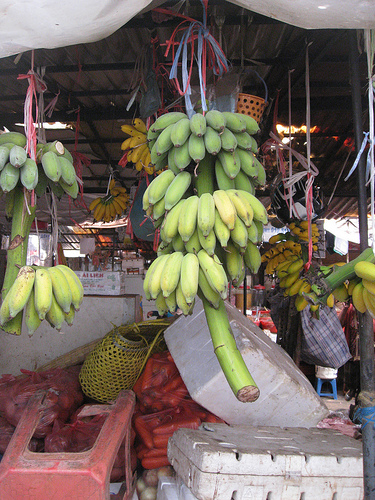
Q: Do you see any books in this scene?
A: No, there are no books.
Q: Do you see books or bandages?
A: No, there are no books or bandages.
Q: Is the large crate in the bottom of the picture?
A: Yes, the crate is in the bottom of the image.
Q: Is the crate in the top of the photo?
A: No, the crate is in the bottom of the image.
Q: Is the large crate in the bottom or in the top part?
A: The crate is in the bottom of the image.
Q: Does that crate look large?
A: Yes, the crate is large.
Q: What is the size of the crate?
A: The crate is large.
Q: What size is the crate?
A: The crate is large.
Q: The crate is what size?
A: The crate is large.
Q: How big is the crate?
A: The crate is large.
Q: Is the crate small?
A: No, the crate is large.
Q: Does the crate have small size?
A: No, the crate is large.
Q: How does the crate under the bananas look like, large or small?
A: The crate is large.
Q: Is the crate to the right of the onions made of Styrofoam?
A: Yes, the crate is made of styrofoam.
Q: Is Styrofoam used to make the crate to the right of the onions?
A: Yes, the crate is made of styrofoam.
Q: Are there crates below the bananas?
A: Yes, there is a crate below the bananas.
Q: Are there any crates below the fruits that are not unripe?
A: Yes, there is a crate below the bananas.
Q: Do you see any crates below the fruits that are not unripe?
A: Yes, there is a crate below the bananas.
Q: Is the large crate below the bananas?
A: Yes, the crate is below the bananas.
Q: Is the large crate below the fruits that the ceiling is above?
A: Yes, the crate is below the bananas.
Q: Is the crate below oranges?
A: No, the crate is below the bananas.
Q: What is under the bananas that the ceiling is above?
A: The crate is under the bananas.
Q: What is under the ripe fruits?
A: The crate is under the bananas.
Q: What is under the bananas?
A: The crate is under the bananas.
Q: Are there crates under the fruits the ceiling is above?
A: Yes, there is a crate under the bananas.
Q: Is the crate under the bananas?
A: Yes, the crate is under the bananas.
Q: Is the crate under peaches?
A: No, the crate is under the bananas.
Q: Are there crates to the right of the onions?
A: Yes, there is a crate to the right of the onions.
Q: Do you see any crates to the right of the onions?
A: Yes, there is a crate to the right of the onions.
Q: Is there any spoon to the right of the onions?
A: No, there is a crate to the right of the onions.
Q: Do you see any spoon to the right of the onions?
A: No, there is a crate to the right of the onions.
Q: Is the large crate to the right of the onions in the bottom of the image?
A: Yes, the crate is to the right of the onions.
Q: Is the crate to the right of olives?
A: No, the crate is to the right of the onions.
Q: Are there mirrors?
A: No, there are no mirrors.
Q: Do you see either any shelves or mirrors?
A: No, there are no mirrors or shelves.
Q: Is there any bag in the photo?
A: Yes, there is a bag.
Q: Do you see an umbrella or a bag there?
A: Yes, there is a bag.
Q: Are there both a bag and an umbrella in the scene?
A: No, there is a bag but no umbrellas.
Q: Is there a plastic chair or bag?
A: Yes, there is a plastic bag.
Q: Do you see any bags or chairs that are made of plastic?
A: Yes, the bag is made of plastic.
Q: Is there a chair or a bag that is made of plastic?
A: Yes, the bag is made of plastic.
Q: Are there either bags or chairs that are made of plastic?
A: Yes, the bag is made of plastic.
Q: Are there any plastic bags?
A: Yes, there is a bag that is made of plastic.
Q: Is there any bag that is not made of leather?
A: Yes, there is a bag that is made of plastic.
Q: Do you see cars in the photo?
A: No, there are no cars.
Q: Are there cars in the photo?
A: No, there are no cars.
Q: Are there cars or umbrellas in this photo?
A: No, there are no cars or umbrellas.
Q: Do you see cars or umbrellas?
A: No, there are no cars or umbrellas.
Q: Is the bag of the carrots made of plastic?
A: Yes, the bag is made of plastic.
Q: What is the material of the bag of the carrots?
A: The bag is made of plastic.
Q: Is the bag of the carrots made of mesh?
A: No, the bag is made of plastic.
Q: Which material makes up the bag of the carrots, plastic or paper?
A: The bag is made of plastic.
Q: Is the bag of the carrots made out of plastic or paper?
A: The bag is made of plastic.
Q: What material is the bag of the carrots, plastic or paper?
A: The bag is made of plastic.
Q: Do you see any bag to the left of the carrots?
A: Yes, there is a bag to the left of the carrots.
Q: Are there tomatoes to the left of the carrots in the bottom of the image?
A: No, there is a bag to the left of the carrots.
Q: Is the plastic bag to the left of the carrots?
A: Yes, the bag is to the left of the carrots.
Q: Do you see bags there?
A: Yes, there is a bag.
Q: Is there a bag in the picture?
A: Yes, there is a bag.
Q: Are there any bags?
A: Yes, there is a bag.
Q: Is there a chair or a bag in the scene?
A: Yes, there is a bag.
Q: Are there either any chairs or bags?
A: Yes, there is a bag.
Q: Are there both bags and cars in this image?
A: No, there is a bag but no cars.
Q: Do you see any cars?
A: No, there are no cars.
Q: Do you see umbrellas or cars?
A: No, there are no cars or umbrellas.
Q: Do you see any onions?
A: Yes, there are onions.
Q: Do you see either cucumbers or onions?
A: Yes, there are onions.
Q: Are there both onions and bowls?
A: No, there are onions but no bowls.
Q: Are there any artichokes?
A: No, there are no artichokes.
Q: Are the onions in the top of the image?
A: No, the onions are in the bottom of the image.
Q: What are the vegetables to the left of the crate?
A: The vegetables are onions.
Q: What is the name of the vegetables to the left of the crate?
A: The vegetables are onions.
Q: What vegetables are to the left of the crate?
A: The vegetables are onions.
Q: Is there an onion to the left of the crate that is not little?
A: Yes, there are onions to the left of the crate.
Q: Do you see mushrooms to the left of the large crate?
A: No, there are onions to the left of the crate.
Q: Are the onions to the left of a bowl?
A: No, the onions are to the left of the crate.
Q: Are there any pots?
A: No, there are no pots.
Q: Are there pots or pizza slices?
A: No, there are no pots or pizza slices.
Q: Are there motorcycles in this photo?
A: No, there are no motorcycles.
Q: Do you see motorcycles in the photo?
A: No, there are no motorcycles.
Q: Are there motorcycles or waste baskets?
A: No, there are no motorcycles or waste baskets.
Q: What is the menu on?
A: The menu is on the wall.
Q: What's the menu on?
A: The menu is on the wall.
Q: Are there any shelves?
A: No, there are no shelves.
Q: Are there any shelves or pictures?
A: No, there are no shelves or pictures.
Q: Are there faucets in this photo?
A: No, there are no faucets.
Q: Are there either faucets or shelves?
A: No, there are no faucets or shelves.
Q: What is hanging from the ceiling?
A: The basket is hanging from the ceiling.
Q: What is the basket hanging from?
A: The basket is hanging from the ceiling.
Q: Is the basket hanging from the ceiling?
A: Yes, the basket is hanging from the ceiling.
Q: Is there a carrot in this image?
A: Yes, there are carrots.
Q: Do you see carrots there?
A: Yes, there are carrots.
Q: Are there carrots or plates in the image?
A: Yes, there are carrots.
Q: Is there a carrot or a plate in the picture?
A: Yes, there are carrots.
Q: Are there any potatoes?
A: No, there are no potatoes.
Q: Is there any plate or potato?
A: No, there are no potatoes or plates.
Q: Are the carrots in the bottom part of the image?
A: Yes, the carrots are in the bottom of the image.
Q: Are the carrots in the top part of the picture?
A: No, the carrots are in the bottom of the image.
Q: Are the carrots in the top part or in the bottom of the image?
A: The carrots are in the bottom of the image.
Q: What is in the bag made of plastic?
A: The carrots are in the bag.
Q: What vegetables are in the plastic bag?
A: The vegetables are carrots.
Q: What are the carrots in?
A: The carrots are in the bag.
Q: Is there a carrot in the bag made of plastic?
A: Yes, there are carrots in the bag.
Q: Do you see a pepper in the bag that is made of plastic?
A: No, there are carrots in the bag.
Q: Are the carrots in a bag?
A: Yes, the carrots are in a bag.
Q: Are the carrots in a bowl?
A: No, the carrots are in a bag.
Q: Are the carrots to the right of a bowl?
A: No, the carrots are to the right of the bag.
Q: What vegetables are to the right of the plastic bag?
A: The vegetables are carrots.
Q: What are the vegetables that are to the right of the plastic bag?
A: The vegetables are carrots.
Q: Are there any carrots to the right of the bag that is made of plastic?
A: Yes, there are carrots to the right of the bag.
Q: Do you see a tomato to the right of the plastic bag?
A: No, there are carrots to the right of the bag.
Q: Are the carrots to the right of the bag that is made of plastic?
A: Yes, the carrots are to the right of the bag.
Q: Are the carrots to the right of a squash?
A: No, the carrots are to the right of the bag.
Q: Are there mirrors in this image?
A: No, there are no mirrors.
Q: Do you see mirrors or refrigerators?
A: No, there are no mirrors or refrigerators.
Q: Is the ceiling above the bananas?
A: Yes, the ceiling is above the bananas.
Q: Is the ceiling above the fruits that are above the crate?
A: Yes, the ceiling is above the bananas.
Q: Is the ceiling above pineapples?
A: No, the ceiling is above the bananas.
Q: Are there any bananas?
A: Yes, there are bananas.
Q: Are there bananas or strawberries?
A: Yes, there are bananas.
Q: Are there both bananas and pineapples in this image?
A: No, there are bananas but no pineapples.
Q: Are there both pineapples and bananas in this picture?
A: No, there are bananas but no pineapples.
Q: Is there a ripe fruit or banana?
A: Yes, there are ripe bananas.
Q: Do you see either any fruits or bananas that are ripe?
A: Yes, the bananas are ripe.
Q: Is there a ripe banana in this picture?
A: Yes, there are ripe bananas.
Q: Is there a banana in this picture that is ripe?
A: Yes, there are bananas that are ripe.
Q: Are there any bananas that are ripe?
A: Yes, there are bananas that are ripe.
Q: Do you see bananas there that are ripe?
A: Yes, there are bananas that are ripe.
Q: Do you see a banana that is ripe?
A: Yes, there are bananas that are ripe.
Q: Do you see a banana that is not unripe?
A: Yes, there are ripe bananas.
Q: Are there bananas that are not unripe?
A: Yes, there are ripe bananas.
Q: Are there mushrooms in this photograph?
A: No, there are no mushrooms.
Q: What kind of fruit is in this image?
A: The fruit is bananas.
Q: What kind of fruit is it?
A: The fruits are bananas.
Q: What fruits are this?
A: These are bananas.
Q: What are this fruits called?
A: These are bananas.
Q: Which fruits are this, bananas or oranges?
A: These are bananas.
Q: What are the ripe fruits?
A: The fruits are bananas.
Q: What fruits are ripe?
A: The fruits are bananas.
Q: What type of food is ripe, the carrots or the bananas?
A: The bananas is ripe.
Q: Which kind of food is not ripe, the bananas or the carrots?
A: The carrots is not ripe.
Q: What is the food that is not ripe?
A: The food is carrots.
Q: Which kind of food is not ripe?
A: The food is carrots.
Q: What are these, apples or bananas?
A: These are bananas.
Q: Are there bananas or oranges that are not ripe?
A: No, there are bananas but they are ripe.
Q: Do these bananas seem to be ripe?
A: Yes, the bananas are ripe.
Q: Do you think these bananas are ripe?
A: Yes, the bananas are ripe.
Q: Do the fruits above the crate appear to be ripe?
A: Yes, the bananas are ripe.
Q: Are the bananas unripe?
A: No, the bananas are ripe.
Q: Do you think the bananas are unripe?
A: No, the bananas are ripe.